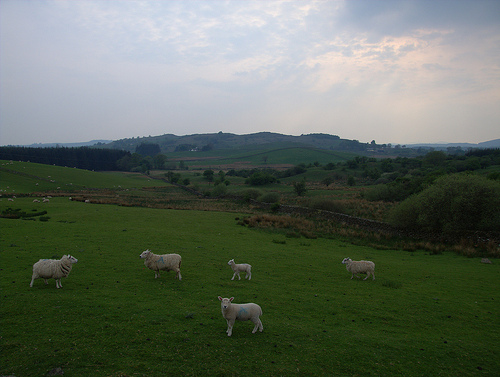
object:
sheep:
[138, 249, 184, 280]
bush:
[377, 276, 405, 290]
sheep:
[342, 256, 377, 281]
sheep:
[226, 259, 253, 281]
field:
[1, 223, 498, 375]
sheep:
[218, 296, 264, 337]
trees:
[0, 130, 499, 230]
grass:
[0, 142, 499, 375]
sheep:
[29, 254, 78, 290]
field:
[0, 143, 493, 374]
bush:
[237, 208, 419, 247]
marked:
[235, 306, 250, 319]